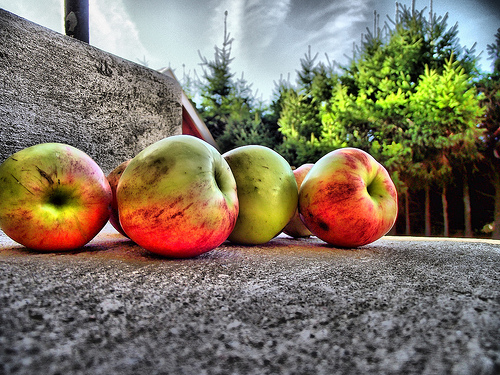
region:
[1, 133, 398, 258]
6 visible red and green apples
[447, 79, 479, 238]
tall tree in the background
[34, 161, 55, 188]
brown scuff mark on apple skin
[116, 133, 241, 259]
apple laying on ground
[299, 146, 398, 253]
apple with green and red peel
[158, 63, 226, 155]
part of a red and white roof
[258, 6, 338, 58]
clouds in the sky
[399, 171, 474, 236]
4 tall tree trunks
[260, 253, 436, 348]
speckled concrete ground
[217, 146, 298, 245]
green apple laying on ground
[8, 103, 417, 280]
Red and green apples on the ground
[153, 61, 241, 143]
Roof of a red house is in the background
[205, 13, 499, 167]
Green trees are in the background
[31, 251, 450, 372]
Ground has a gray stone texture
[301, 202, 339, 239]
Apple has a black spot on it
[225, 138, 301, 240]
Apple is all green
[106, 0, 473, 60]
The sky is cloudy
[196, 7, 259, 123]
Pine tree is in the background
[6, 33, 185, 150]
A gray stone wall is behind apples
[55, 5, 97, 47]
A black pipe is sticking out of stone wall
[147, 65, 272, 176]
Evergreen trees in the background.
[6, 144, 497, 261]
Apples sitting on stone.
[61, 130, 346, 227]
Fruit.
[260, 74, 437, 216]
Green trees behind the fruit.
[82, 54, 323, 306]
Red and green colored apples.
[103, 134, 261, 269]
An apple.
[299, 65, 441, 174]
Lots of evergreen trees.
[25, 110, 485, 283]
A bunch of apples laying around.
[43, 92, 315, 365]
Stone surface with fruit sitting on it.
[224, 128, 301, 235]
One green apple among the others.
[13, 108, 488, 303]
six apples in the picture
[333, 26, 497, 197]
trees in the background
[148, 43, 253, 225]
a house in the background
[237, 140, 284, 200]
the apple is green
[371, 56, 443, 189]
the trees are green and red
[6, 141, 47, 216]
the apple is bruised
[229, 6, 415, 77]
there are clouds in the sky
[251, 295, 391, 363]
this is grey and white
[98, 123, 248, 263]
the apple is green and red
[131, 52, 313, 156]
the roof is white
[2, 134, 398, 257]
Green and red apples on a bench.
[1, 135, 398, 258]
Six apples on a gray bench.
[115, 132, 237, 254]
One green and red bruised apple.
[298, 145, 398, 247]
Green and red apple with bruise.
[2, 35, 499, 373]
Gray bench with apples.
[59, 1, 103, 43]
Pool adjacent to the patio.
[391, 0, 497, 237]
Green trees beside the patio.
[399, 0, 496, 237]
Four trees with green leaves.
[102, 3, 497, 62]
Clouds in the blue sky.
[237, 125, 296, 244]
Green apple with red and green apples.